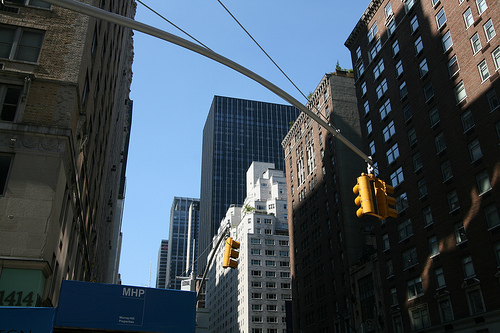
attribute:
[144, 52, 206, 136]
this is the sky — clear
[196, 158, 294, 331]
building — white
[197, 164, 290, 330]
casing — white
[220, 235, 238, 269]
stoplight — yellow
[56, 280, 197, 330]
box — blue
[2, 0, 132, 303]
building — stone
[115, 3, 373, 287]
sky — blue, clear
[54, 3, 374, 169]
pole — silver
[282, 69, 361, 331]
building — dark brown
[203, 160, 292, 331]
building — white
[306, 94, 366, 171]
post — metal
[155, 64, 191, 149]
sky — blue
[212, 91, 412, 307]
building — brown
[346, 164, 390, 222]
light — yellow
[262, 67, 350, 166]
pole — metal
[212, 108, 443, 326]
buildings — tall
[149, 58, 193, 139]
sky — blue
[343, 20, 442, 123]
building — brick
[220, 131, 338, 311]
building — tall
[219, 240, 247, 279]
light — yellow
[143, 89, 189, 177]
sky — blue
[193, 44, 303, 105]
pole — metal